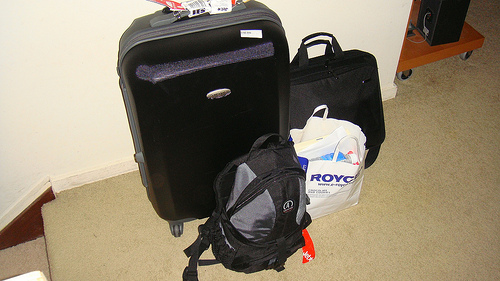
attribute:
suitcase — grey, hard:
[117, 1, 290, 237]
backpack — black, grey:
[183, 134, 312, 281]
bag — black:
[289, 32, 385, 168]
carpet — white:
[305, 1, 499, 280]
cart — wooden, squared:
[398, 22, 485, 79]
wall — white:
[0, 1, 137, 229]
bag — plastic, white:
[292, 104, 370, 220]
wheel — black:
[169, 220, 184, 239]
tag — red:
[150, 1, 184, 11]